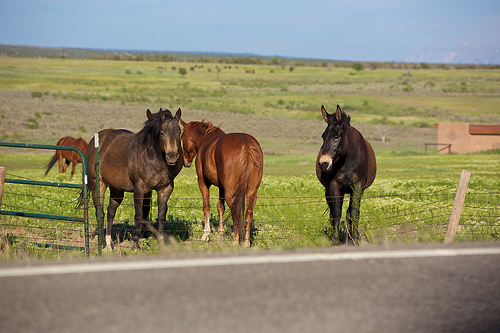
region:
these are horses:
[54, 80, 495, 270]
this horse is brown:
[174, 97, 242, 197]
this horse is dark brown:
[92, 111, 160, 201]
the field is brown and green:
[215, 45, 297, 143]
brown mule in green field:
[87, 95, 185, 227]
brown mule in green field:
[295, 106, 373, 241]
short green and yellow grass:
[390, 165, 421, 180]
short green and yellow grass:
[233, 71, 267, 101]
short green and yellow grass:
[395, 188, 426, 209]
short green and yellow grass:
[385, 73, 440, 110]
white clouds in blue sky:
[390, 22, 441, 54]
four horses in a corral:
[5, 59, 491, 259]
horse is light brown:
[176, 113, 270, 247]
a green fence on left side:
[1, 132, 101, 259]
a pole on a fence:
[438, 157, 480, 246]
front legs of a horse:
[324, 187, 364, 244]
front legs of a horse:
[194, 183, 226, 242]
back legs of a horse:
[221, 184, 257, 251]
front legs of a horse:
[129, 183, 176, 250]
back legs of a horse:
[89, 185, 126, 251]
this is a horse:
[178, 106, 280, 233]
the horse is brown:
[178, 108, 288, 247]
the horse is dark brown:
[298, 95, 386, 240]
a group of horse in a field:
[8, 10, 495, 256]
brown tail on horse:
[225, 139, 260, 248]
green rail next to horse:
[6, 115, 111, 253]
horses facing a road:
[0, 77, 478, 329]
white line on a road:
[11, 219, 491, 285]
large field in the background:
[5, 25, 496, 232]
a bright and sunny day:
[9, 15, 480, 317]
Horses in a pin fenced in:
[41, 88, 396, 237]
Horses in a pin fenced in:
[45, 98, 387, 239]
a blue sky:
[8, 15, 498, 59]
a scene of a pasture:
[3, 4, 498, 331]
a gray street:
[8, 224, 499, 331]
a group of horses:
[32, 89, 407, 258]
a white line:
[8, 227, 495, 280]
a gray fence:
[83, 173, 498, 270]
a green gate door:
[2, 118, 114, 257]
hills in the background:
[5, 32, 490, 92]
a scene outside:
[8, 7, 493, 321]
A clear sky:
[1, 0, 498, 81]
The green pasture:
[2, 53, 496, 246]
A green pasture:
[2, 55, 498, 227]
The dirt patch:
[6, 80, 430, 157]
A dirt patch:
[2, 75, 429, 150]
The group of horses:
[36, 92, 392, 269]